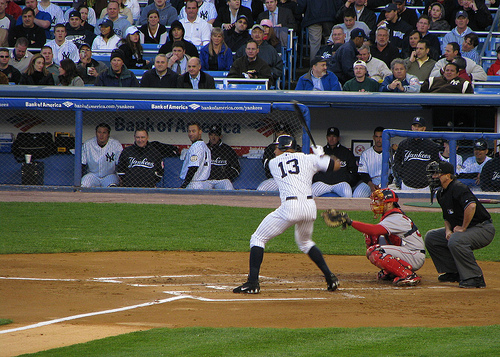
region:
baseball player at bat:
[228, 99, 361, 311]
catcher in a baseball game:
[320, 175, 434, 287]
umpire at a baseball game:
[416, 152, 496, 296]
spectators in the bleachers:
[7, 5, 488, 100]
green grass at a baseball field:
[156, 328, 497, 355]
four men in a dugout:
[70, 112, 254, 193]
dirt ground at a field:
[16, 285, 103, 304]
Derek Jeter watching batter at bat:
[174, 120, 219, 197]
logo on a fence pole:
[137, 96, 288, 118]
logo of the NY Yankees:
[123, 150, 163, 173]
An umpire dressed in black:
[423, 162, 491, 285]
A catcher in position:
[338, 179, 434, 286]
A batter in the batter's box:
[170, 121, 347, 312]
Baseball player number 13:
[245, 124, 348, 289]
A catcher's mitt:
[313, 202, 362, 239]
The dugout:
[14, 95, 494, 205]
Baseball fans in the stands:
[0, 2, 499, 82]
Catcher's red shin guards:
[364, 245, 428, 289]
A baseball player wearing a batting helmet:
[248, 127, 339, 262]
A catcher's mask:
[358, 186, 408, 221]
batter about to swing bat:
[227, 96, 337, 292]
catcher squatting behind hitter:
[337, 187, 423, 282]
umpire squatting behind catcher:
[419, 159, 491, 286]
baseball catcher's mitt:
[324, 206, 343, 228]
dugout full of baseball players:
[2, 94, 497, 203]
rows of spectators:
[0, 3, 493, 91]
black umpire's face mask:
[426, 160, 439, 192]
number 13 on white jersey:
[277, 157, 301, 176]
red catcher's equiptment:
[365, 245, 411, 285]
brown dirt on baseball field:
[5, 256, 497, 348]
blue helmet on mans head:
[275, 133, 300, 150]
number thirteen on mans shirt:
[271, 159, 308, 175]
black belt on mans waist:
[276, 195, 318, 202]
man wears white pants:
[257, 211, 296, 236]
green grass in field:
[122, 209, 177, 236]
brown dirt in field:
[125, 251, 176, 272]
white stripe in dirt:
[73, 303, 145, 318]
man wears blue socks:
[244, 250, 266, 272]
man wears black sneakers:
[224, 278, 267, 303]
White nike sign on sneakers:
[238, 285, 250, 292]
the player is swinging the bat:
[225, 90, 356, 295]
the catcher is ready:
[327, 165, 430, 302]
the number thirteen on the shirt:
[238, 102, 330, 238]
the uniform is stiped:
[242, 125, 345, 302]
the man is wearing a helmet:
[233, 121, 310, 173]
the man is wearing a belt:
[255, 180, 330, 215]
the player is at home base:
[220, 83, 337, 308]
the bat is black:
[287, 90, 331, 155]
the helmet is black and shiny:
[252, 104, 302, 155]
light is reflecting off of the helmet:
[257, 118, 306, 158]